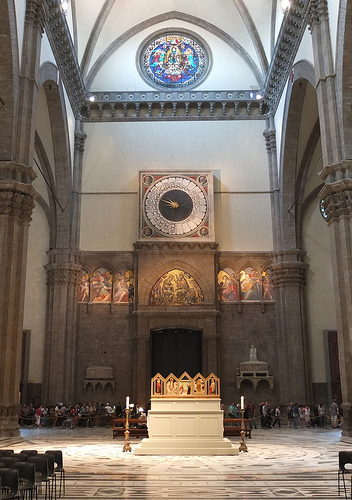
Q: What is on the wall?
A: A clock.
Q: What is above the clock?
A: Stained glass.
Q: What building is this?
A: A church.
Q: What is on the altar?
A: Paintings.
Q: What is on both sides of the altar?
A: Candles.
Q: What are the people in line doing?
A: Viewing displays of the church.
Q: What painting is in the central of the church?
A: Two figures.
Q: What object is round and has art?
A: Painting at the top of the church.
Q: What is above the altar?
A: Decorative windows.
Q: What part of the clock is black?
A: Center.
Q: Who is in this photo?
A: Groups of tourists.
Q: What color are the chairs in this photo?
A: Black.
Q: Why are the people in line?
A: They are on a tour.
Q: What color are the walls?
A: Tan.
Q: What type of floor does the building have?
A: Marble.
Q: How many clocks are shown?
A: Just one.